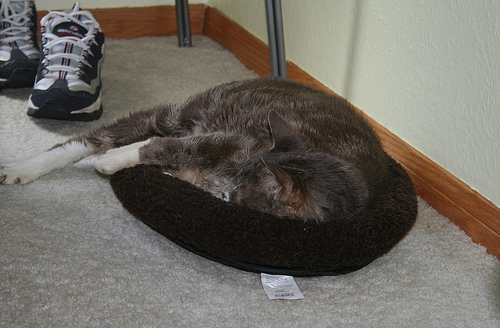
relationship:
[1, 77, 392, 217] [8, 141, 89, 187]
cat has paw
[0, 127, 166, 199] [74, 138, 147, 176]
paws has paw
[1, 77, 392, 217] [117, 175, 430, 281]
cat in cat bed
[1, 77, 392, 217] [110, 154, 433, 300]
cat napping in cat bed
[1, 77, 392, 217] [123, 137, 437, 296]
cat sleeping in bed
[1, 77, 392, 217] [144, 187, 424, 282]
cat laying on bed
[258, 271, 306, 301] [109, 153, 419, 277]
white tag attached to bed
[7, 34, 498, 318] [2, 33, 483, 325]
carpet covering floor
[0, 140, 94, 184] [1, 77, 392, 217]
paw belonging to cat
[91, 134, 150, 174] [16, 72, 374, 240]
paw belonging to cat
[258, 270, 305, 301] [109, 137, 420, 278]
tag attached to cat bed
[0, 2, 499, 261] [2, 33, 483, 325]
trim bordering floor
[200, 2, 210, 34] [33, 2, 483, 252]
gap appearing in moulding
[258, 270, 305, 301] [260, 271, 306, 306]
tag printed on white tag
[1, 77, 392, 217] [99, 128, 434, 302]
cat lying on top of bed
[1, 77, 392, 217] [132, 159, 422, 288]
cat lying on top of bed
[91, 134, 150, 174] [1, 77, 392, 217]
paw belonging to cat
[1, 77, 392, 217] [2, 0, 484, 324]
cat lying inside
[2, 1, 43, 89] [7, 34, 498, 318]
shoe sitting on top of carpet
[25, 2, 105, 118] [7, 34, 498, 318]
shoe sitting on top of carpet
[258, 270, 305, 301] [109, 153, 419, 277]
tag attached to bed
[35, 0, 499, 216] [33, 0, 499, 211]
white paint on walls